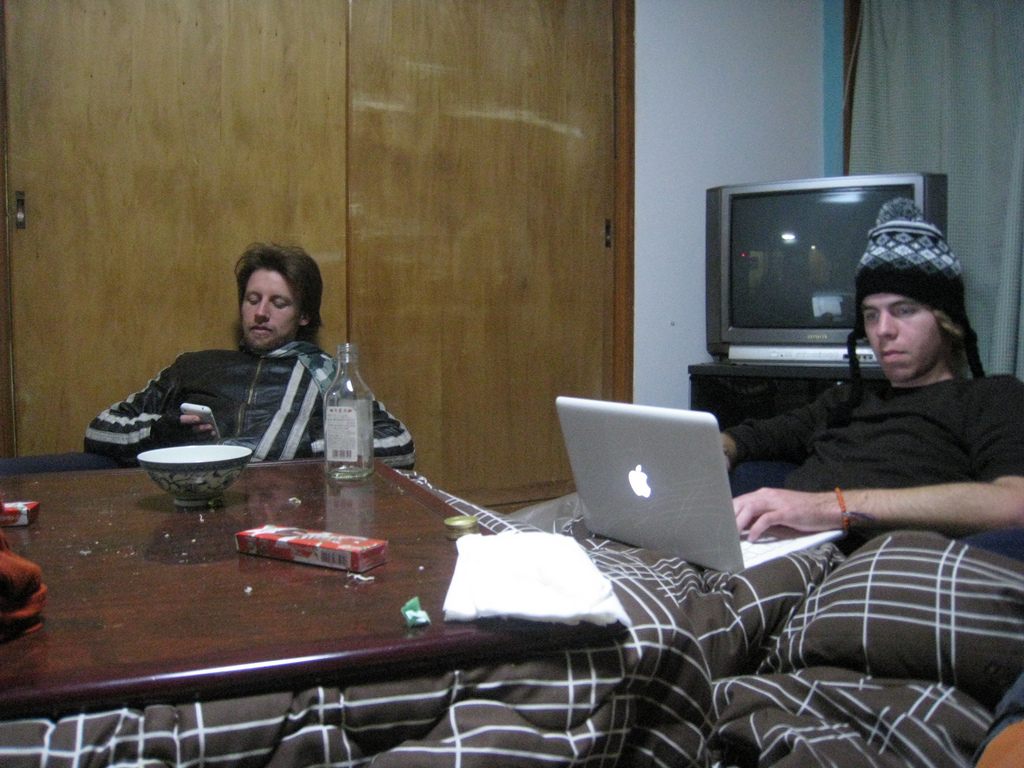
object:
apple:
[622, 458, 660, 505]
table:
[677, 357, 912, 435]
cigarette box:
[226, 515, 396, 574]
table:
[0, 445, 635, 721]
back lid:
[551, 390, 749, 576]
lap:
[921, 600, 971, 638]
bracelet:
[822, 476, 876, 548]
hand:
[722, 469, 857, 577]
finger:
[733, 487, 783, 546]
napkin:
[437, 525, 642, 639]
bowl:
[124, 429, 259, 511]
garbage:
[382, 586, 455, 638]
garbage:
[437, 501, 484, 544]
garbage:
[339, 554, 386, 593]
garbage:
[155, 509, 221, 565]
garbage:
[225, 570, 273, 603]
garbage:
[5, 483, 49, 534]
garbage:
[60, 519, 114, 580]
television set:
[701, 170, 950, 369]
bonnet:
[842, 193, 993, 401]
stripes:
[266, 359, 314, 447]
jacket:
[72, 337, 423, 471]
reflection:
[774, 217, 828, 263]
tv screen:
[727, 184, 919, 330]